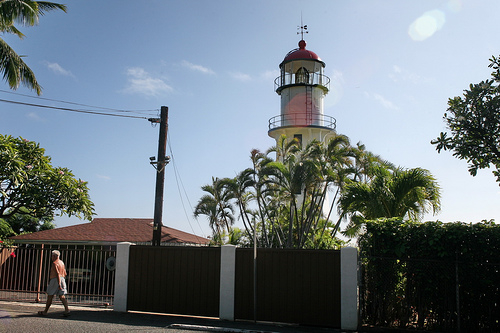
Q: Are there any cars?
A: No, there are no cars.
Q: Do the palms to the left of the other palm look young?
A: Yes, the palms are young.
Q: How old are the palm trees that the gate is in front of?
A: The palms are young.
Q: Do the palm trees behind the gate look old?
A: No, the palm trees are young.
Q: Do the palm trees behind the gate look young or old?
A: The palms are young.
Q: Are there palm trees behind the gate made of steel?
A: Yes, there are palm trees behind the gate.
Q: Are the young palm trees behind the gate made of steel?
A: Yes, the palms are behind the gate.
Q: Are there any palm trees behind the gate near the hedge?
A: Yes, there are palm trees behind the gate.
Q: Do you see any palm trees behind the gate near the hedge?
A: Yes, there are palm trees behind the gate.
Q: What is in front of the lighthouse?
A: The palms are in front of the light house.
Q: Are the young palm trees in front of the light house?
A: Yes, the palms are in front of the light house.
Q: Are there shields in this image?
A: No, there are no shields.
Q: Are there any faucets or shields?
A: No, there are no shields or faucets.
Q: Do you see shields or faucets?
A: No, there are no shields or faucets.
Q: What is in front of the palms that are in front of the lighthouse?
A: The gate is in front of the palm trees.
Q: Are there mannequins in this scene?
A: No, there are no mannequins.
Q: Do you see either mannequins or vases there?
A: No, there are no mannequins or vases.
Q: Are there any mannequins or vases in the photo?
A: No, there are no mannequins or vases.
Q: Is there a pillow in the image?
A: No, there are no pillows.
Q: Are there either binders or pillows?
A: No, there are no pillows or binders.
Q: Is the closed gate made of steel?
A: Yes, the gate is made of steel.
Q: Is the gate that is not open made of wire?
A: No, the gate is made of steel.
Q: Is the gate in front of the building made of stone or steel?
A: The gate is made of steel.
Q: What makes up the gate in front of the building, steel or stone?
A: The gate is made of steel.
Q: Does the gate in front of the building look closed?
A: Yes, the gate is closed.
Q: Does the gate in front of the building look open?
A: No, the gate is closed.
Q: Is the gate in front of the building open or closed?
A: The gate is closed.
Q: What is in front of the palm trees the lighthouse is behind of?
A: The gate is in front of the palms.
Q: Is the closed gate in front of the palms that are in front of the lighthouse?
A: Yes, the gate is in front of the palm trees.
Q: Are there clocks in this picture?
A: No, there are no clocks.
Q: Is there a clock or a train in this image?
A: No, there are no clocks or trains.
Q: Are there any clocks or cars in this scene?
A: No, there are no cars or clocks.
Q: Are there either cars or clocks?
A: No, there are no cars or clocks.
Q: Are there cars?
A: No, there are no cars.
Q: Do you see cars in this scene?
A: No, there are no cars.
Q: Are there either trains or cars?
A: No, there are no cars or trains.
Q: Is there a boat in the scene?
A: No, there are no boats.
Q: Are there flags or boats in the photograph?
A: No, there are no boats or flags.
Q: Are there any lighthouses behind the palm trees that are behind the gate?
A: Yes, there is a lighthouse behind the palms.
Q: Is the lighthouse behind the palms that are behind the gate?
A: Yes, the lighthouse is behind the palm trees.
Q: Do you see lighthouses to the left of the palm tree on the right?
A: Yes, there is a lighthouse to the left of the palm tree.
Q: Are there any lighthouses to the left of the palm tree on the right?
A: Yes, there is a lighthouse to the left of the palm tree.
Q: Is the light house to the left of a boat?
A: No, the light house is to the left of a palm tree.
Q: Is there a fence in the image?
A: Yes, there is a fence.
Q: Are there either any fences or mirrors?
A: Yes, there is a fence.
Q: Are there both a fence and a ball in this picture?
A: No, there is a fence but no balls.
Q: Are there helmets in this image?
A: No, there are no helmets.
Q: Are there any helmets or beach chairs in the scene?
A: No, there are no helmets or beach chairs.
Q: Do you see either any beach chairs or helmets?
A: No, there are no helmets or beach chairs.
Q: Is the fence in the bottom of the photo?
A: Yes, the fence is in the bottom of the image.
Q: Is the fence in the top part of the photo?
A: No, the fence is in the bottom of the image.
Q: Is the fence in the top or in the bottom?
A: The fence is in the bottom of the image.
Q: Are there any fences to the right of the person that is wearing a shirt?
A: Yes, there is a fence to the right of the person.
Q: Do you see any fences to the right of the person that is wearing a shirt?
A: Yes, there is a fence to the right of the person.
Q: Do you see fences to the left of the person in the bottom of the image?
A: No, the fence is to the right of the person.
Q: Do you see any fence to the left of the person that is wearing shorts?
A: No, the fence is to the right of the person.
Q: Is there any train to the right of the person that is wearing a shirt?
A: No, there is a fence to the right of the person.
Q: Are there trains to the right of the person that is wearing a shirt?
A: No, there is a fence to the right of the person.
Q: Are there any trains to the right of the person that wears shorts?
A: No, there is a fence to the right of the person.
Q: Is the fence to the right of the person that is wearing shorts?
A: Yes, the fence is to the right of the person.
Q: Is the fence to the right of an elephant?
A: No, the fence is to the right of the person.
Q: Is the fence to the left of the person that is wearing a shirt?
A: No, the fence is to the right of the person.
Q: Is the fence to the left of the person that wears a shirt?
A: No, the fence is to the right of the person.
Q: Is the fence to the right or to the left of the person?
A: The fence is to the right of the person.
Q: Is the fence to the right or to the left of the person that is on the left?
A: The fence is to the right of the person.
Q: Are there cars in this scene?
A: No, there are no cars.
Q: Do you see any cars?
A: No, there are no cars.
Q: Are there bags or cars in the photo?
A: No, there are no cars or bags.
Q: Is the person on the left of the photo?
A: Yes, the person is on the left of the image.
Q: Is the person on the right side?
A: No, the person is on the left of the image.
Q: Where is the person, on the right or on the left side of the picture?
A: The person is on the left of the image.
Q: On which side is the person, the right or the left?
A: The person is on the left of the image.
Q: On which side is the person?
A: The person is on the left of the image.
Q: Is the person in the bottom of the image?
A: Yes, the person is in the bottom of the image.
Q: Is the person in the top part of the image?
A: No, the person is in the bottom of the image.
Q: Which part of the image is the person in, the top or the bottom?
A: The person is in the bottom of the image.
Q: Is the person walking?
A: Yes, the person is walking.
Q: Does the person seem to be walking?
A: Yes, the person is walking.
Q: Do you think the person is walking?
A: Yes, the person is walking.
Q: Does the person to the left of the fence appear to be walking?
A: Yes, the person is walking.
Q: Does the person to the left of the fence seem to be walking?
A: Yes, the person is walking.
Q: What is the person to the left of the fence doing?
A: The person is walking.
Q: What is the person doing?
A: The person is walking.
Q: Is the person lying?
A: No, the person is walking.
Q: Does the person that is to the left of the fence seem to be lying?
A: No, the person is walking.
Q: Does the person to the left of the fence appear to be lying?
A: No, the person is walking.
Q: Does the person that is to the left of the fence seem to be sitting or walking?
A: The person is walking.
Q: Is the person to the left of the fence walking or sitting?
A: The person is walking.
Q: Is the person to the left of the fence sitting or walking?
A: The person is walking.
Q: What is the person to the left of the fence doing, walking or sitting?
A: The person is walking.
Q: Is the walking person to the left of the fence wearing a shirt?
A: Yes, the person is wearing a shirt.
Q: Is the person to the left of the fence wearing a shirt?
A: Yes, the person is wearing a shirt.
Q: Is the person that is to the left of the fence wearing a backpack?
A: No, the person is wearing a shirt.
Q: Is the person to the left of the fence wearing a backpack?
A: No, the person is wearing a shirt.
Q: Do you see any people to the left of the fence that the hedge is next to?
A: Yes, there is a person to the left of the fence.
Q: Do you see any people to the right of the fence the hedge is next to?
A: No, the person is to the left of the fence.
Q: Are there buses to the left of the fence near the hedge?
A: No, there is a person to the left of the fence.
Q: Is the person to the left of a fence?
A: Yes, the person is to the left of a fence.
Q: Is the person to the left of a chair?
A: No, the person is to the left of a fence.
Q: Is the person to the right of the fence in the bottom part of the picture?
A: No, the person is to the left of the fence.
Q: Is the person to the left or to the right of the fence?
A: The person is to the left of the fence.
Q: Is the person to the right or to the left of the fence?
A: The person is to the left of the fence.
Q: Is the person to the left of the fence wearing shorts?
A: Yes, the person is wearing shorts.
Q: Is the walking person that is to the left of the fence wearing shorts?
A: Yes, the person is wearing shorts.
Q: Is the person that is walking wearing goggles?
A: No, the person is wearing shorts.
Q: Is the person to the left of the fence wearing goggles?
A: No, the person is wearing shorts.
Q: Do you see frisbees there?
A: No, there are no frisbees.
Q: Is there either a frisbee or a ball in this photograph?
A: No, there are no frisbees or balls.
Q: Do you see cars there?
A: No, there are no cars.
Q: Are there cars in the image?
A: No, there are no cars.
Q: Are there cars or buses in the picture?
A: No, there are no cars or buses.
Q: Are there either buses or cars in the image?
A: No, there are no cars or buses.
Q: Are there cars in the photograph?
A: No, there are no cars.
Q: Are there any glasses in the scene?
A: No, there are no glasses.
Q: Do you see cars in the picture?
A: No, there are no cars.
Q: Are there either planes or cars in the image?
A: No, there are no cars or planes.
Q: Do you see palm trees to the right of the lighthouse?
A: Yes, there is a palm tree to the right of the lighthouse.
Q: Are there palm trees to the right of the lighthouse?
A: Yes, there is a palm tree to the right of the lighthouse.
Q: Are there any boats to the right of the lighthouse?
A: No, there is a palm tree to the right of the lighthouse.